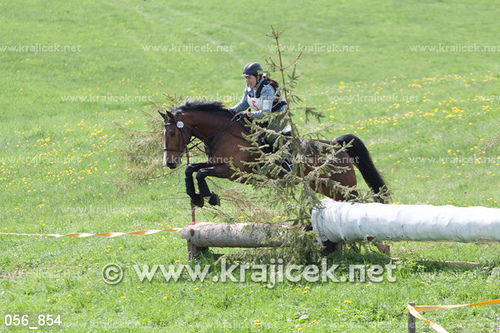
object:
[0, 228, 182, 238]
rope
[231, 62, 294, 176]
man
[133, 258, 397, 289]
address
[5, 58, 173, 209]
flowers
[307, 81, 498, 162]
flowers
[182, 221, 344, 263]
poll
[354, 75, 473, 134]
yello grass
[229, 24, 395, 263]
fur tree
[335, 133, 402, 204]
tail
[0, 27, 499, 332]
grass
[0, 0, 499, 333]
field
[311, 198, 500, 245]
wrapping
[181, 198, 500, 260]
pole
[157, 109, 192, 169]
head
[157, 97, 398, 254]
horse